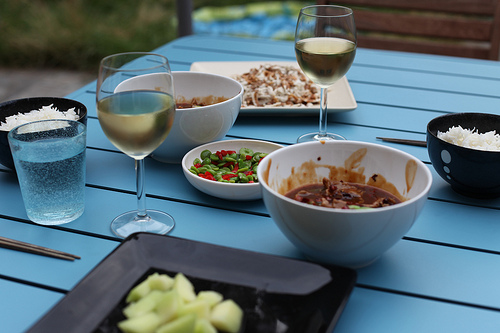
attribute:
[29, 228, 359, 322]
bowl — Black, square 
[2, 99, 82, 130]
rice — white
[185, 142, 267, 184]
peppers — red, green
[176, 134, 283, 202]
bowl — small, flat, white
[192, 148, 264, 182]
vegetables — white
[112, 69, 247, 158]
bowl — White 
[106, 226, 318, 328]
plate — black, square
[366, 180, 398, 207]
sauce — barbecue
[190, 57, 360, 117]
plate — square, white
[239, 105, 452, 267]
bowl — white, large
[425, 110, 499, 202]
bowl — black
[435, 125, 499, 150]
rice — white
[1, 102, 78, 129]
rice — white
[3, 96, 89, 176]
bowl — black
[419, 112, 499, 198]
black bowl — small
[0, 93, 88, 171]
black bowl — small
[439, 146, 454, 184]
circles — three, gray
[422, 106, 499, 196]
bowl — black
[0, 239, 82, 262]
chopsticks — wooden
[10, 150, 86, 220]
water — seltzer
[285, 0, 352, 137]
glass — tall, stemmed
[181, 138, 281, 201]
dish — small, white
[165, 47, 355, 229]
plate — White, square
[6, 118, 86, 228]
glass — small, Clear, Speckled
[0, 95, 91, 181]
bowl — black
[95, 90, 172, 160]
wine — white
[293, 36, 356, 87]
wine — white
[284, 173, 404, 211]
gravy — brown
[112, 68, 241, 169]
bowl — White , round 